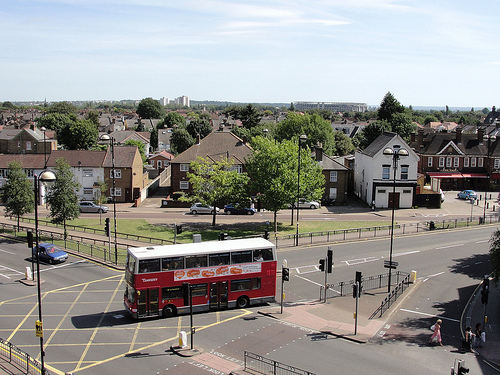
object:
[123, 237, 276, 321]
bus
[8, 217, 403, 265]
grass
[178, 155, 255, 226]
tree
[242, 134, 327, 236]
tree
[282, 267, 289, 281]
streetlight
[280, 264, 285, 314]
pole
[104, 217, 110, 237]
streetlight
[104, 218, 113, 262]
pole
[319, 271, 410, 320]
fence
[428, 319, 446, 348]
woman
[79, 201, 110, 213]
car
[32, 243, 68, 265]
car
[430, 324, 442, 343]
dress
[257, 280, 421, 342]
concrete area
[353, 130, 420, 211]
house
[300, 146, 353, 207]
house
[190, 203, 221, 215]
car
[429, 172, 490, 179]
awning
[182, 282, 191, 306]
streetlight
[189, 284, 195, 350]
pole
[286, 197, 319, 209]
car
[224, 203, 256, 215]
car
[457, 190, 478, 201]
car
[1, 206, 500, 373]
street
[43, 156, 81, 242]
tree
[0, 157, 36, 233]
tree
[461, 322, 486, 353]
people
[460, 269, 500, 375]
sidewalk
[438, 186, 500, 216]
parking lot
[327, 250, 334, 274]
streetlight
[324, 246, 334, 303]
pole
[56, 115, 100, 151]
tree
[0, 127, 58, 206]
house